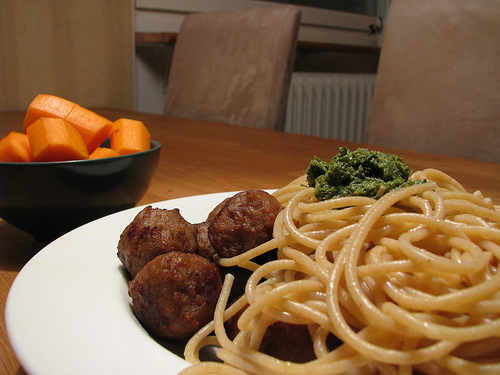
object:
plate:
[3, 187, 499, 374]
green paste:
[304, 145, 427, 201]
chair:
[164, 3, 302, 132]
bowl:
[0, 134, 161, 243]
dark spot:
[108, 125, 120, 135]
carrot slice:
[109, 117, 152, 156]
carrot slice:
[23, 93, 114, 156]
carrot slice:
[27, 115, 91, 162]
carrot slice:
[87, 145, 120, 159]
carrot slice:
[0, 130, 32, 162]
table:
[0, 107, 499, 374]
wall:
[265, 94, 386, 154]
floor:
[184, 145, 224, 166]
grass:
[3, 88, 154, 171]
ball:
[197, 187, 285, 261]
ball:
[117, 204, 198, 278]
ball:
[128, 250, 223, 339]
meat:
[222, 205, 261, 233]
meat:
[137, 222, 174, 247]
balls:
[230, 295, 343, 363]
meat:
[140, 259, 202, 322]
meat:
[271, 328, 300, 354]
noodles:
[178, 167, 499, 374]